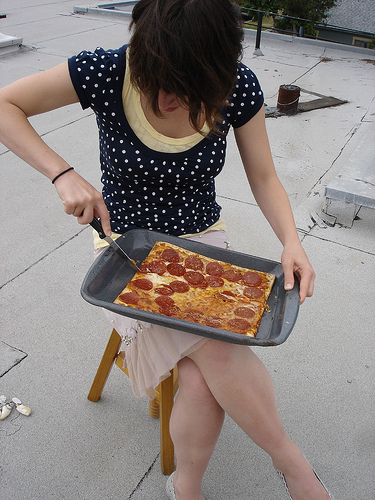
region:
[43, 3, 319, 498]
girl cutting the pizza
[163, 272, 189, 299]
pepperoni on the pizza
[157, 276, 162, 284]
cheese on the pizza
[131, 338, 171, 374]
white skirt girl is wearing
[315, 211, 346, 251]
cracks in the road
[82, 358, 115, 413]
leg of the chair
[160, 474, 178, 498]
heel of the shoe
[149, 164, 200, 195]
polkadots on the shirt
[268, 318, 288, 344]
pan the pizza is on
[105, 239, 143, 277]
knife the girl is holding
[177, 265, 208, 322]
this pizza has pepperoni on it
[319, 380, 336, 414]
This cement has a gray color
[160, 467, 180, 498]
this person is wearing white pumps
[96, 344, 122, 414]
There is a wooden chair here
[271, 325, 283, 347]
There is a black pan here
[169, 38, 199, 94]
This person has dark brown hair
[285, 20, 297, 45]
There is a black fence here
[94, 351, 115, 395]
There is wood that is there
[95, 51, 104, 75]
There is a black t-shirt here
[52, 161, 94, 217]
This woman has a bracelet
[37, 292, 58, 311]
Small part of the gray sidewalk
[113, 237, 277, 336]
Square-shaped pizza in the pan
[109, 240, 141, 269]
Silver part of the knife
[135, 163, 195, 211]
Dark blue and white dotted shirt of the female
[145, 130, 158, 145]
Yellow undershirt of female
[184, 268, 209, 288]
Red pepperoni on the pizza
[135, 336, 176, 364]
Small part of the girl's beige skirt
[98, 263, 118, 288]
Small section of the gray pan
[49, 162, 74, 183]
Black bracelet located on girl's arm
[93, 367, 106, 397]
Small part of the wooden stool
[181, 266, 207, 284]
pepperoni on the pizza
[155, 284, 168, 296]
pepperoni on the pizza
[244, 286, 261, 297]
pepperoni on the pizza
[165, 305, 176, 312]
pepperoni on the pizza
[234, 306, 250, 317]
pepperoni on the pizza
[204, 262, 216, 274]
pepperoni on the pizza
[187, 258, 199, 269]
pepperoni on the pizza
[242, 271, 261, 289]
pepperoni on the pizza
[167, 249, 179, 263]
pepperoni on the pizza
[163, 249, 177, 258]
pepperoni on the pizza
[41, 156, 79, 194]
woman is wearing a black bracelet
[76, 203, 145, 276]
woman is holding a knife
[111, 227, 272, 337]
pizza with pepperoni slices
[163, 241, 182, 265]
round red pepperoni slice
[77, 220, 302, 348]
silver tray with pizza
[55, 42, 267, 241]
woman wearing a blue polka dot shirt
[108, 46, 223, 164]
woman is wearing a yellow tank top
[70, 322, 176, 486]
woman is sitting on a wooden stool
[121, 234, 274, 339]
a large pizza with cheese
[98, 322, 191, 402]
a pink skirt with ruffles